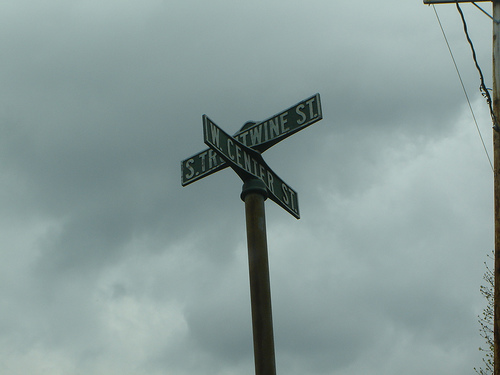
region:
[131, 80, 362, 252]
A street sign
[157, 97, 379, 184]
Go straight for "S. Tri Twine St."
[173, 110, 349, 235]
"W. Center St."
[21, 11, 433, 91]
There are clouds in the sky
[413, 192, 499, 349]
Branches sticking out of the corner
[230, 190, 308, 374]
Pole is brown from rust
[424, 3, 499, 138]
Wires on a pole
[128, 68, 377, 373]
The pole is pointing in several directions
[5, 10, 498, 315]
There are multiple clouds in the sky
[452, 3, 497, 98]
This wire is not straight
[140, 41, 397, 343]
street signs on a pole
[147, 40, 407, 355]
street signs on a metal pole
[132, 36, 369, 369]
two street signs on a pole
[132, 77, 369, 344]
two signs on a pole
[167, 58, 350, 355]
two street signs on a metal pole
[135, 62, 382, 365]
two signs on a metal pole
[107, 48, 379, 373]
a pole with signs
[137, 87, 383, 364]
a pole with street signs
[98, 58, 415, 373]
a metal pole with signs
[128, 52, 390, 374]
a metal pole with street signs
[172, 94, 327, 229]
Signs at crossroads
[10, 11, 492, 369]
Sky behind signs is gray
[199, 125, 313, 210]
W. Center St sign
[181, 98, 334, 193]
Both signs are small and green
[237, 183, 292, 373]
Metal pole beneath signs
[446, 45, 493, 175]
Wires behind sign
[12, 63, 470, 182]
One dark gray cloud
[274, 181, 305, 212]
ST stands for street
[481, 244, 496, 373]
Tree alongside of signpost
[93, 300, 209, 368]
Lighter portion of sky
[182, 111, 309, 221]
green and white street signs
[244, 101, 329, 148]
green and white street signs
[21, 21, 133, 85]
gray and white cloues in sky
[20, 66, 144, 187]
gray and white cloues in sky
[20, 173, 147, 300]
gray and white cloues in sky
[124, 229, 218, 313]
gray and white cloues in sky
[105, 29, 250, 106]
gray and white cloues in sky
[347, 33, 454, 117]
gray and white cloues in sky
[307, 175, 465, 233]
gray and white cloues in sky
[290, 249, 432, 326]
gray and white cloues in sky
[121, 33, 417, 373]
street sign on pole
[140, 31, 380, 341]
street sign on metal pole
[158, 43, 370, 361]
two street signs on metal pole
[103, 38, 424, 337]
two signs on pole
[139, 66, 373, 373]
two street signs on pole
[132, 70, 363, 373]
two signs on metal pole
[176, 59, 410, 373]
pole with street signs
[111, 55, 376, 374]
pole with two street signs